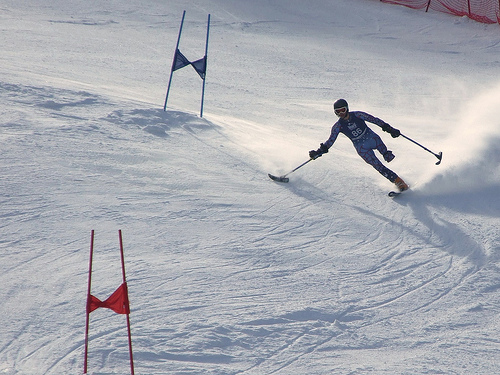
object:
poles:
[113, 229, 141, 375]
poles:
[160, 8, 188, 114]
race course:
[0, 1, 499, 375]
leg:
[351, 140, 399, 185]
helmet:
[331, 99, 349, 118]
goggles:
[333, 106, 348, 116]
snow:
[0, 0, 499, 375]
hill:
[0, 0, 499, 375]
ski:
[386, 175, 418, 198]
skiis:
[265, 174, 290, 183]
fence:
[376, 0, 500, 27]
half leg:
[372, 141, 395, 164]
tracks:
[347, 261, 481, 334]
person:
[308, 98, 410, 194]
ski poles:
[263, 150, 326, 182]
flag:
[78, 227, 138, 372]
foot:
[394, 182, 412, 193]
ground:
[0, 1, 498, 375]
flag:
[160, 8, 212, 119]